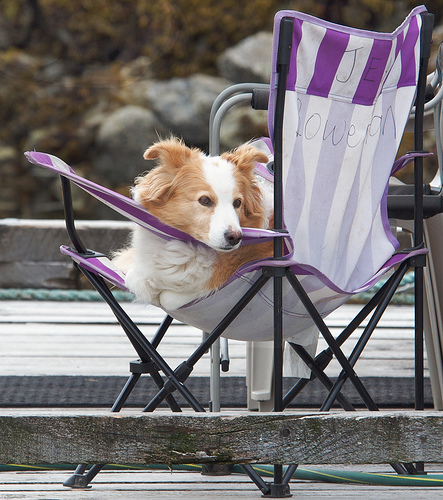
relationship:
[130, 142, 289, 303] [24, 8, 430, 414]
dog on chair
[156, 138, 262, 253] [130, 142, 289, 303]
head of dog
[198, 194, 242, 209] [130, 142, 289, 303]
brown eyes of dog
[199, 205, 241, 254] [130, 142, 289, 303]
mouth of dog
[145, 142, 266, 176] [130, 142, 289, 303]
ears of dog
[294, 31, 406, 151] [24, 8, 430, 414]
writing on chair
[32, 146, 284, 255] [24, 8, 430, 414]
arm rest of chair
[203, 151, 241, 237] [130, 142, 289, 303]
white stripe on dog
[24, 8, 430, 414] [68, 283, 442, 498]
chair has metal poles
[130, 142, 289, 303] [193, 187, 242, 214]
dog has brown eyes